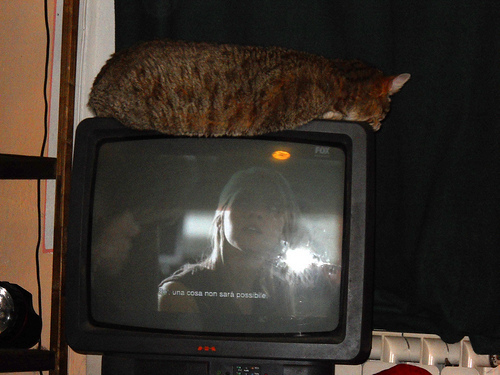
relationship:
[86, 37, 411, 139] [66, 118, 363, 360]
cat on tv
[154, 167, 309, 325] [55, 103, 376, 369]
woman on screen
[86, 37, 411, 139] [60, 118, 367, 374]
cat lying on television